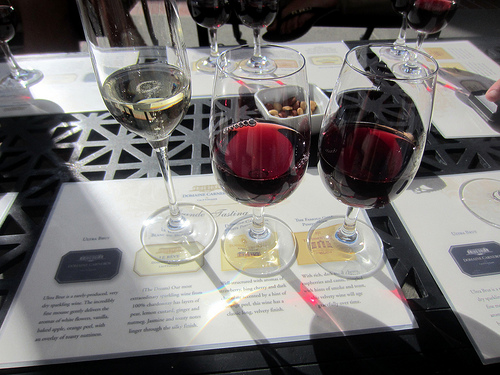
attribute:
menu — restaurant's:
[4, 170, 424, 370]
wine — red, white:
[222, 123, 415, 200]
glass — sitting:
[127, 122, 409, 289]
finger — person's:
[484, 80, 498, 112]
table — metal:
[5, 35, 499, 374]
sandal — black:
[261, 4, 322, 42]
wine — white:
[97, 87, 180, 132]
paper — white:
[0, 151, 417, 343]